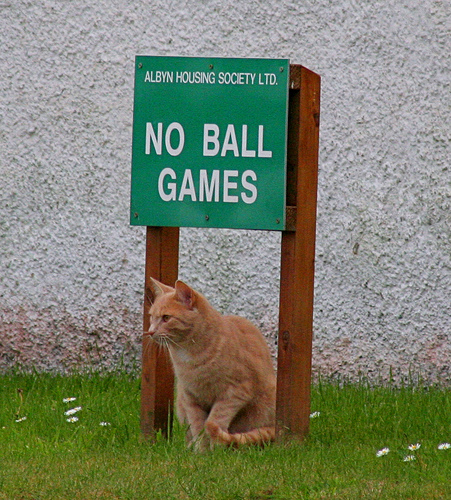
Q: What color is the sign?
A: Green.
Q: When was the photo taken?
A: Daylight.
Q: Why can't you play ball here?
A: The sign says so.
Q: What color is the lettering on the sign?
A: White.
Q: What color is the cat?
A: Yellow.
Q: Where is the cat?
A: Under the sign.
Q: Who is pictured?
A: A cat.